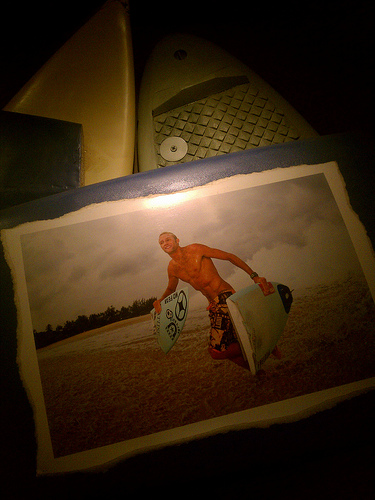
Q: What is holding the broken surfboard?
A: The man.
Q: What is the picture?
A: Of the man.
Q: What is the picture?
A: Of the man.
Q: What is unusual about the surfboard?
A: It's in two pieces.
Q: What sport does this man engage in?
A: Surfing.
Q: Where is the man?
A: Ocean.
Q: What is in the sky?
A: Clouds.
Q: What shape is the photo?
A: Rectangle.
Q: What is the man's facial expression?
A: Smiling.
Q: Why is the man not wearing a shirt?
A: Because he's swimming/surfing.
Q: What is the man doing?
A: Running out of the water.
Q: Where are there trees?
A: In the distance.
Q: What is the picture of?
A: Surfer.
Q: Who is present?
A: A man.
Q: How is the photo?
A: Clear.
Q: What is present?
A: A painting.